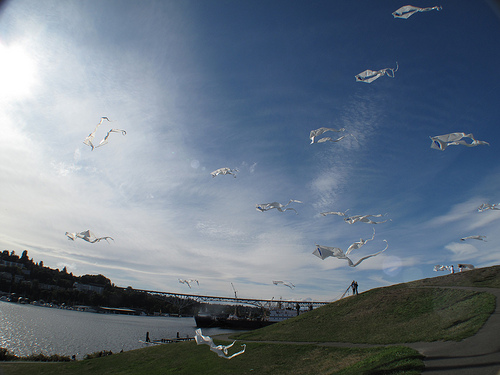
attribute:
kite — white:
[392, 2, 440, 21]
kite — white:
[353, 66, 399, 86]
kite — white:
[427, 131, 487, 151]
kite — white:
[256, 199, 303, 216]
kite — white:
[211, 165, 239, 180]